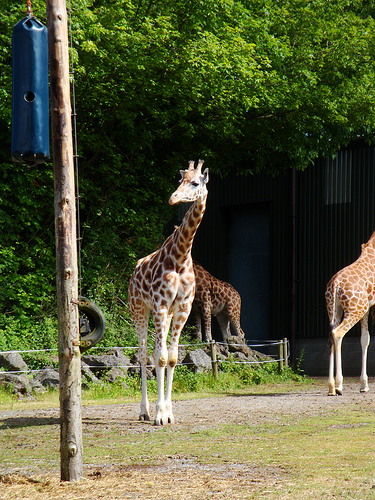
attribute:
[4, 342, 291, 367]
fence — wire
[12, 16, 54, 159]
bag — blue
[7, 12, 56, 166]
bag — blue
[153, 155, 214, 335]
giraffe — tall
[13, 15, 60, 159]
bag — blue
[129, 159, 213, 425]
giraffe — thing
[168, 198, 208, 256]
neck — long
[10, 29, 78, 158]
bag — blue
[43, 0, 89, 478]
pole — tall, wooden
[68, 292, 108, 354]
tube — black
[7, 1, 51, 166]
bag — blue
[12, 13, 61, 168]
bag — blue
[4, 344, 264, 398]
rocks — gray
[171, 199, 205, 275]
neck — bent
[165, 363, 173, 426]
leg — white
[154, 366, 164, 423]
leg — white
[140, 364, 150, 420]
leg — white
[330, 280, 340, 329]
tail — long